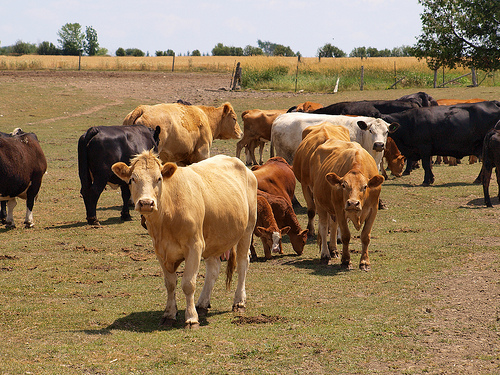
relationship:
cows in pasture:
[4, 92, 496, 310] [2, 56, 499, 374]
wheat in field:
[3, 56, 500, 73] [2, 52, 499, 374]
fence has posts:
[231, 65, 494, 97] [232, 60, 246, 91]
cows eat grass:
[4, 92, 496, 310] [7, 77, 499, 372]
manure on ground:
[163, 83, 270, 107] [1, 71, 500, 374]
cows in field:
[4, 92, 496, 310] [2, 52, 499, 374]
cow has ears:
[307, 136, 385, 275] [320, 167, 387, 191]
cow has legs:
[109, 155, 259, 322] [158, 235, 252, 327]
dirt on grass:
[26, 70, 254, 108] [7, 77, 499, 372]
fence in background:
[231, 65, 494, 97] [4, 2, 500, 92]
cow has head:
[307, 136, 385, 275] [330, 168, 372, 219]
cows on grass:
[4, 92, 496, 310] [7, 77, 499, 372]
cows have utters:
[4, 92, 496, 310] [206, 248, 239, 267]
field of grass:
[2, 52, 499, 374] [7, 77, 499, 372]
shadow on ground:
[63, 301, 239, 350] [1, 71, 500, 374]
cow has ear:
[109, 155, 259, 322] [158, 160, 179, 185]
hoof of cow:
[230, 300, 251, 311] [109, 155, 259, 322]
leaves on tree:
[429, 6, 500, 57] [418, 0, 499, 81]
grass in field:
[7, 77, 499, 372] [2, 52, 499, 374]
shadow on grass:
[63, 301, 239, 350] [7, 77, 499, 372]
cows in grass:
[4, 92, 496, 310] [7, 77, 499, 372]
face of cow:
[120, 152, 169, 216] [109, 155, 259, 322]